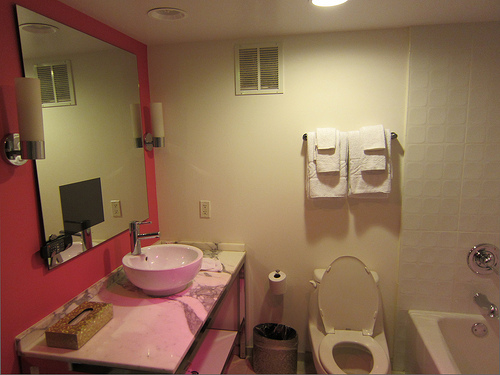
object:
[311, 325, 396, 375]
seat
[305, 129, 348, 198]
towels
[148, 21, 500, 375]
wall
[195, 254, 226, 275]
tissue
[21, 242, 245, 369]
counter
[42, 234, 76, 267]
holder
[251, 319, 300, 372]
can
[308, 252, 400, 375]
toilet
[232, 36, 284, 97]
vent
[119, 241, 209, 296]
sink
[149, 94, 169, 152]
light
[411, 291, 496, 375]
tub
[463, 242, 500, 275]
plumbing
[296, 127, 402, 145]
bar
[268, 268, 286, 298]
paper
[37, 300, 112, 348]
box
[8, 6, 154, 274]
mirror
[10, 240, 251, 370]
countertop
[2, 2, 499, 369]
bathroom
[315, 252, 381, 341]
lid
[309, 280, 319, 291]
handle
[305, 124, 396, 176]
up